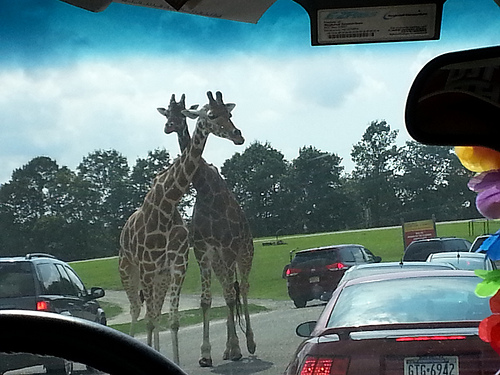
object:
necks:
[150, 132, 209, 207]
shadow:
[216, 356, 272, 373]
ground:
[119, 297, 332, 375]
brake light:
[395, 334, 465, 342]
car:
[402, 236, 472, 263]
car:
[422, 251, 491, 271]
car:
[285, 266, 499, 375]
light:
[285, 267, 291, 275]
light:
[299, 353, 339, 371]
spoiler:
[317, 322, 486, 341]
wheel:
[294, 294, 309, 307]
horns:
[204, 89, 215, 104]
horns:
[214, 89, 223, 106]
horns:
[167, 93, 176, 108]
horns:
[180, 94, 188, 106]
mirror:
[372, 255, 382, 262]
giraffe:
[117, 90, 248, 367]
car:
[424, 250, 494, 277]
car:
[0, 251, 108, 326]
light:
[35, 298, 50, 312]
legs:
[168, 289, 182, 367]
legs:
[200, 267, 214, 368]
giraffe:
[158, 93, 258, 365]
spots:
[140, 220, 185, 270]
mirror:
[88, 287, 105, 299]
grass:
[268, 239, 280, 261]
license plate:
[401, 350, 463, 374]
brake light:
[328, 260, 345, 270]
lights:
[323, 263, 345, 272]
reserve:
[0, 0, 499, 375]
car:
[281, 244, 383, 309]